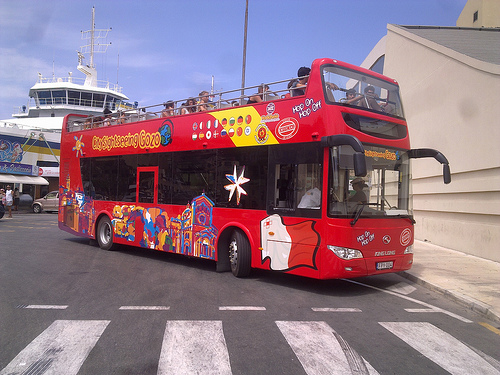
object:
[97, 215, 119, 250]
rear wheel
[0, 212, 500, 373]
grey road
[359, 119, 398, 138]
sign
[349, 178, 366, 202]
driver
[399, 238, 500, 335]
sidewalk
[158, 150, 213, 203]
window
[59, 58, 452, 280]
bus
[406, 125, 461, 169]
ground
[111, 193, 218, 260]
drawings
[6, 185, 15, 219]
person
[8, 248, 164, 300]
tarmac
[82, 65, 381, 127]
people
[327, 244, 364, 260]
light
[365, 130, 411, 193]
ground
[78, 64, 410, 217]
mirror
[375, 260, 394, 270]
license plate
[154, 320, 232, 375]
line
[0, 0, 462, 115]
sky.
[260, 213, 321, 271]
flag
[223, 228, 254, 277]
wheel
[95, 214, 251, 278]
tires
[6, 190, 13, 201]
shirt